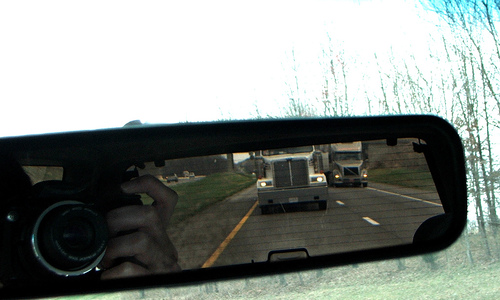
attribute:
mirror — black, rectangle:
[31, 151, 449, 225]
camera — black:
[16, 196, 102, 267]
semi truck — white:
[257, 157, 346, 206]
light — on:
[310, 176, 329, 190]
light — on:
[332, 171, 348, 184]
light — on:
[361, 169, 376, 181]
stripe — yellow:
[233, 216, 252, 232]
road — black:
[259, 224, 353, 243]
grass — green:
[208, 181, 235, 195]